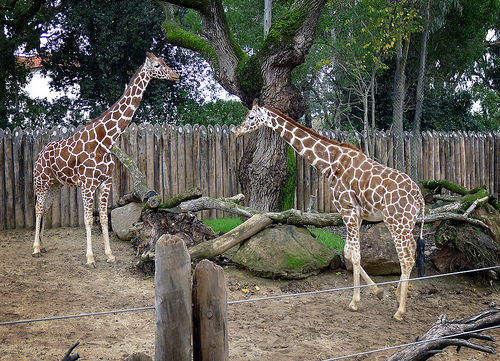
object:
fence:
[0, 115, 499, 231]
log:
[171, 194, 494, 264]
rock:
[231, 222, 341, 279]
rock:
[431, 218, 498, 281]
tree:
[167, 0, 432, 231]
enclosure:
[0, 124, 498, 361]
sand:
[1, 224, 498, 359]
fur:
[342, 159, 379, 199]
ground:
[2, 227, 499, 356]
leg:
[343, 215, 417, 306]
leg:
[32, 181, 111, 256]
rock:
[111, 201, 148, 241]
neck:
[92, 65, 147, 143]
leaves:
[323, 0, 428, 72]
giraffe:
[235, 100, 425, 322]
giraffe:
[32, 51, 181, 270]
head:
[235, 97, 266, 138]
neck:
[262, 105, 330, 175]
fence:
[1, 234, 500, 360]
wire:
[0, 265, 499, 327]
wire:
[320, 324, 500, 360]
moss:
[166, 11, 320, 110]